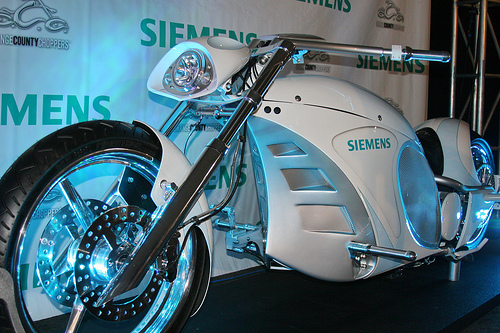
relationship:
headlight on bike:
[145, 33, 253, 104] [6, 63, 498, 284]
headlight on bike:
[145, 33, 253, 104] [4, 32, 494, 329]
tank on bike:
[291, 68, 450, 271] [4, 32, 494, 329]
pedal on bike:
[356, 239, 423, 269] [4, 32, 494, 329]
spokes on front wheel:
[33, 169, 188, 326] [1, 110, 213, 330]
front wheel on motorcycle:
[1, 110, 213, 330] [8, 29, 420, 311]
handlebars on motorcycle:
[294, 39, 491, 100] [125, 29, 477, 241]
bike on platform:
[4, 32, 494, 329] [4, 237, 484, 329]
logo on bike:
[343, 136, 395, 153] [4, 32, 494, 329]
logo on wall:
[0, 84, 120, 134] [3, 2, 434, 322]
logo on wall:
[138, 17, 258, 49] [3, 2, 434, 322]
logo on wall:
[354, 52, 426, 74] [3, 2, 434, 322]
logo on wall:
[299, 0, 351, 12] [3, 2, 434, 322]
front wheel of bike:
[1, 110, 213, 330] [4, 32, 494, 329]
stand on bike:
[423, 238, 481, 299] [4, 32, 494, 329]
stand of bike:
[423, 238, 481, 299] [4, 32, 494, 329]